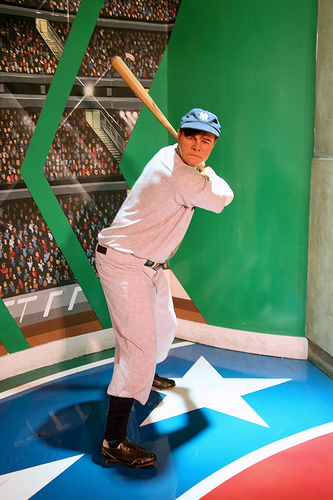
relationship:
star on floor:
[136, 352, 292, 431] [17, 337, 310, 496]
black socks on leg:
[103, 391, 134, 442] [77, 321, 165, 451]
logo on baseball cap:
[199, 111, 210, 122] [178, 107, 222, 138]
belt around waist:
[88, 233, 174, 279] [94, 226, 179, 277]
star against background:
[136, 352, 296, 439] [2, 351, 322, 496]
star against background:
[1, 451, 89, 499] [2, 351, 322, 496]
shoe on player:
[97, 434, 158, 469] [91, 107, 237, 497]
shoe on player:
[151, 370, 176, 391] [91, 107, 237, 497]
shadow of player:
[29, 373, 214, 478] [91, 107, 237, 497]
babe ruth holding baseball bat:
[102, 107, 235, 469] [108, 54, 183, 142]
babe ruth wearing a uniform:
[95, 107, 236, 469] [95, 144, 226, 406]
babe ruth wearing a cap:
[95, 107, 236, 469] [181, 102, 218, 132]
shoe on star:
[151, 370, 174, 390] [140, 356, 291, 428]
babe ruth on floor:
[95, 107, 236, 469] [0, 335, 331, 498]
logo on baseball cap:
[199, 112, 210, 119] [178, 107, 221, 137]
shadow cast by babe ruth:
[29, 373, 214, 478] [95, 107, 236, 469]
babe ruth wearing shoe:
[95, 107, 236, 469] [97, 434, 158, 469]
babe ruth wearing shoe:
[95, 107, 236, 469] [151, 370, 176, 391]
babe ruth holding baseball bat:
[95, 107, 236, 469] [109, 53, 205, 173]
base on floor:
[3, 308, 309, 378] [0, 335, 331, 498]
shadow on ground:
[29, 373, 214, 478] [2, 339, 322, 492]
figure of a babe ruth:
[92, 52, 233, 466] [95, 107, 236, 469]